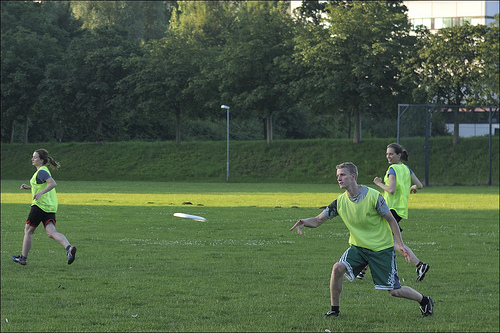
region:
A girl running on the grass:
[8, 143, 83, 273]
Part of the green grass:
[86, 227, 136, 282]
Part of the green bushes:
[245, 145, 276, 171]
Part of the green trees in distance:
[105, 55, 212, 105]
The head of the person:
[332, 156, 362, 188]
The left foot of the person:
[10, 250, 30, 265]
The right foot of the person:
[65, 240, 75, 265]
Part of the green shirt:
[350, 212, 360, 237]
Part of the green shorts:
[375, 262, 385, 275]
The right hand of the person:
[288, 216, 310, 237]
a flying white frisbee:
[171, 208, 208, 223]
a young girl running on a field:
[11, 144, 81, 267]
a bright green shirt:
[331, 189, 397, 249]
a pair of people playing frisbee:
[291, 138, 440, 320]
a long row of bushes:
[0, 140, 499, 183]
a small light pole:
[220, 103, 232, 178]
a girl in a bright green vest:
[8, 144, 80, 273]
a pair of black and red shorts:
[26, 205, 54, 225]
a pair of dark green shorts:
[338, 245, 398, 285]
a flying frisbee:
[171, 212, 207, 224]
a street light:
[216, 98, 234, 189]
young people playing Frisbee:
[10, 128, 459, 323]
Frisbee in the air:
[165, 203, 215, 228]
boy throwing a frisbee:
[168, 155, 405, 319]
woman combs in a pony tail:
[7, 142, 84, 276]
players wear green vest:
[10, 136, 462, 331]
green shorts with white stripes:
[339, 243, 401, 293]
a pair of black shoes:
[319, 289, 436, 327]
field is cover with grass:
[4, 180, 498, 329]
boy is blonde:
[289, 156, 385, 237]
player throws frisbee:
[289, 160, 436, 317]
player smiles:
[372, 142, 425, 250]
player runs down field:
[11, 146, 82, 266]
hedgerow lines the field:
[0, 135, 499, 183]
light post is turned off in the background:
[216, 100, 235, 178]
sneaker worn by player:
[417, 293, 432, 317]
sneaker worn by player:
[323, 304, 343, 316]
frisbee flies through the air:
[169, 208, 206, 225]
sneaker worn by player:
[62, 239, 80, 266]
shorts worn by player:
[25, 199, 60, 230]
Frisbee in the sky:
[166, 204, 211, 234]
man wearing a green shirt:
[326, 189, 411, 250]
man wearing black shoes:
[415, 290, 435, 319]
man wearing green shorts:
[341, 231, 403, 292]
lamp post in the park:
[211, 93, 233, 185]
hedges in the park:
[102, 138, 255, 170]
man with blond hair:
[331, 155, 361, 184]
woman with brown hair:
[385, 144, 407, 161]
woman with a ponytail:
[29, 148, 59, 172]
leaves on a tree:
[184, 23, 311, 88]